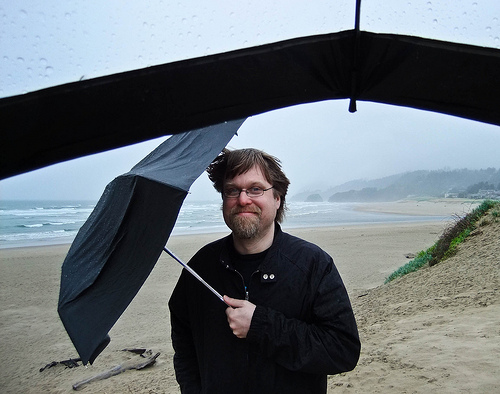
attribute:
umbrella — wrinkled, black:
[57, 100, 258, 368]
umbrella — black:
[56, 114, 251, 365]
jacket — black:
[158, 127, 373, 392]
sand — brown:
[390, 302, 471, 381]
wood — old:
[72, 345, 161, 390]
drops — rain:
[0, 0, 495, 97]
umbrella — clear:
[0, 1, 499, 178]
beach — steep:
[7, 169, 490, 392]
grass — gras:
[436, 197, 472, 254]